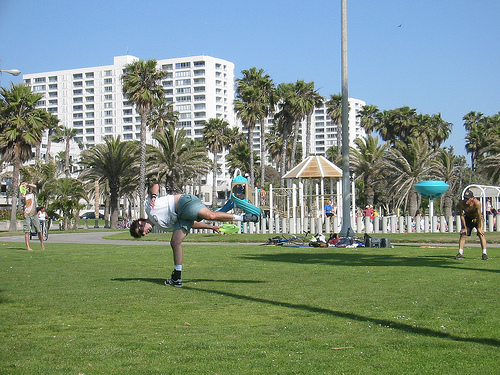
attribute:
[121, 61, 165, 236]
tree — tall , green 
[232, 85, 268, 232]
tree — tall , green 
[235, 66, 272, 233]
tree — tall , green 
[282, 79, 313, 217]
tree — tall , green 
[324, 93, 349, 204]
tree — tall , green 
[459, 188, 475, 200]
hat — black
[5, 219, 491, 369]
area — Flat, grassy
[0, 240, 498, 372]
grassy field — green , grassy 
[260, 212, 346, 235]
fence — small, white, wooden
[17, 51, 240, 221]
building — large, white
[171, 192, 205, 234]
shorts — green 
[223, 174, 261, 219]
slide — green 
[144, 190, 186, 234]
shirt — white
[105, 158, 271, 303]
man — bending over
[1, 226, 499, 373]
field — grassy 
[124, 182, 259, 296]
man — doing kick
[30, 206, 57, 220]
shirt — white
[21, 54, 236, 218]
hotel — large, white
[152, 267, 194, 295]
shoe — black , white 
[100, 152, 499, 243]
playground — large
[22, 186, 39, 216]
shirt — brown